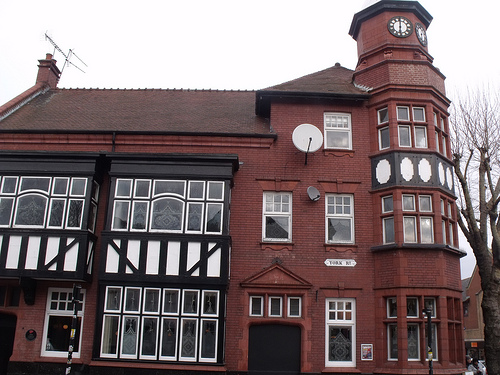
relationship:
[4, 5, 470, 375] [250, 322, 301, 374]
building has door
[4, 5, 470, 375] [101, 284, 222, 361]
building has windows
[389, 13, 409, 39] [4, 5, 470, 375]
clock on building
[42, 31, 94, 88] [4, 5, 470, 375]
antennas on building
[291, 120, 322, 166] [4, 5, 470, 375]
satellite dish on building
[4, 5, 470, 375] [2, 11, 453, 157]
building has top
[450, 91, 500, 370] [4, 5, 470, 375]
tree next to building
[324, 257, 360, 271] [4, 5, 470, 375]
sign on building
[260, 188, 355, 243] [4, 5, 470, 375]
windows in building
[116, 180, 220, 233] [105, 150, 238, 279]
windows in window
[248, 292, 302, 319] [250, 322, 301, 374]
windows above door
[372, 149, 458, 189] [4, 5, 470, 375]
design on building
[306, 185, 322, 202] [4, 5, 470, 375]
satellite dish on building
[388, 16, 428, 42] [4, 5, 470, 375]
clocks on top of building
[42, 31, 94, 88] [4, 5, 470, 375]
antennas on top of building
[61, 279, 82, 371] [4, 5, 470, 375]
light pole on side of building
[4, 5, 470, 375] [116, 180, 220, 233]
building has windows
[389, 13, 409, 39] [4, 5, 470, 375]
clock on top of building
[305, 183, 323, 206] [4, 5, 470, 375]
satellite dish on building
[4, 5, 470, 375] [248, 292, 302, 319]
building has windows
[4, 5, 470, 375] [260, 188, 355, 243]
building has windows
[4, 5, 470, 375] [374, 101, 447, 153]
building has windows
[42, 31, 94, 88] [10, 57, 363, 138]
antennas on roof